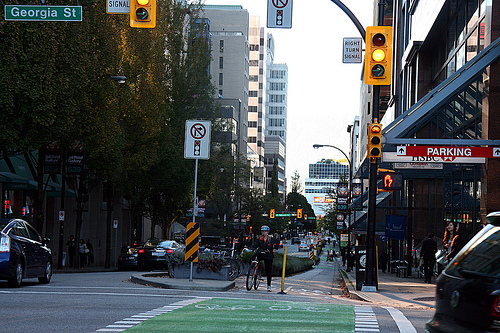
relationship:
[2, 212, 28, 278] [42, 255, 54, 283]
car has wheel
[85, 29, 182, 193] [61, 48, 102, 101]
tree has branches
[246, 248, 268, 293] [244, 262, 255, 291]
bike has wheel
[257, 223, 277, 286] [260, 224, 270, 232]
person has helmet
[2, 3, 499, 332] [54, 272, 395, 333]
city has crosswalk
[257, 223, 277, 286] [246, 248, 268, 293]
person on bike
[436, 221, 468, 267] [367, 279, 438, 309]
lady on corner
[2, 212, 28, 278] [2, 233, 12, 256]
car has lights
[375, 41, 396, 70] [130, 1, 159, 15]
part of a light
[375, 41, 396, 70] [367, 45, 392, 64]
part of a light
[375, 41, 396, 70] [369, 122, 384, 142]
part of a light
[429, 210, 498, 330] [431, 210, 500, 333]
back of a car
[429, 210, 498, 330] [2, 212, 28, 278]
back of a car